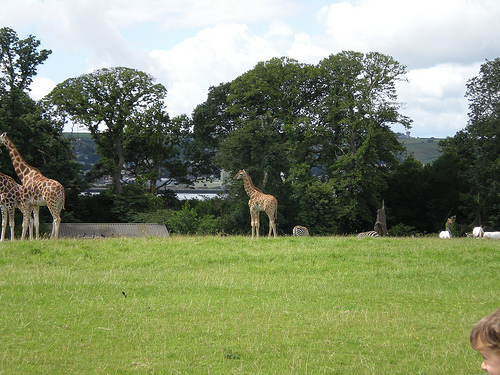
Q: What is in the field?
A: Grass.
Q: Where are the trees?
A: In the back.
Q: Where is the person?
A: In the lower right side.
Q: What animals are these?
A: Giraffes.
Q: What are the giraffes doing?
A: Standing.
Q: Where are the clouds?
A: In the sky.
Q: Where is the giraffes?
A: On the side of the tree.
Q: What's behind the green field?
A: Trees.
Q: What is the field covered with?
A: Grass.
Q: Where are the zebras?
A: In the background.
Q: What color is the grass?
A: Green.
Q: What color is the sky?
A: Blue.